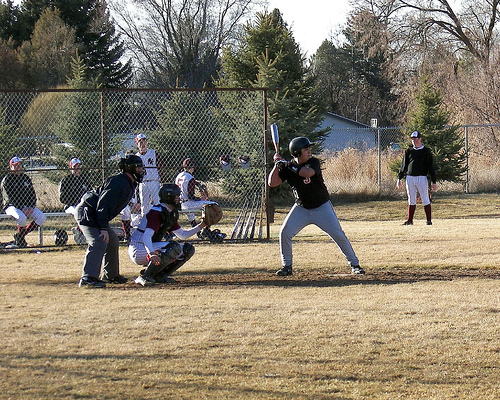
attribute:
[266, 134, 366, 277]
player — ready, concentrating, standing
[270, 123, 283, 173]
bat — baseball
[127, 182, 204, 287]
catcher — concentrating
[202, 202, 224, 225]
mit — thick, baseball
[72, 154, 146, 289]
umpire — waiting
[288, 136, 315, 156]
helmet — black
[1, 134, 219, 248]
people — watching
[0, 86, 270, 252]
fence — metal, chain link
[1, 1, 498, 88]
sky — cloudy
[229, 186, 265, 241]
bats — spare, row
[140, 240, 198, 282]
guards — protection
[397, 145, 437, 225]
uniform — long sleeved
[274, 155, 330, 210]
shirt — black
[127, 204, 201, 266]
uniform — white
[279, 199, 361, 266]
pants — gray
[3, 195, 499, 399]
field — brown, grassy, dry